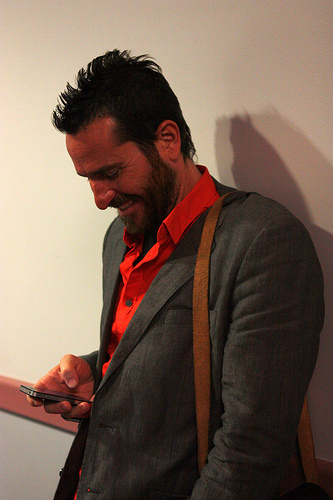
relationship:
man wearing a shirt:
[28, 45, 329, 499] [65, 156, 220, 499]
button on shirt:
[123, 296, 133, 307] [65, 156, 220, 499]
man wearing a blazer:
[28, 45, 329, 499] [44, 175, 328, 499]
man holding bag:
[28, 45, 329, 499] [191, 184, 323, 499]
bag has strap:
[191, 184, 323, 499] [191, 187, 318, 488]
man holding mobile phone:
[28, 45, 329, 499] [19, 382, 93, 409]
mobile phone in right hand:
[19, 382, 93, 409] [27, 354, 99, 422]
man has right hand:
[28, 45, 329, 499] [27, 354, 99, 422]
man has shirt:
[28, 45, 329, 499] [65, 156, 220, 499]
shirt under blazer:
[65, 156, 220, 499] [44, 175, 328, 499]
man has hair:
[28, 45, 329, 499] [52, 49, 199, 165]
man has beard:
[28, 45, 329, 499] [93, 164, 179, 237]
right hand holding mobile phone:
[27, 354, 99, 422] [19, 382, 93, 409]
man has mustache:
[28, 45, 329, 499] [106, 193, 144, 207]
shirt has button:
[65, 156, 220, 499] [123, 296, 133, 307]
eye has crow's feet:
[98, 170, 122, 180] [120, 153, 141, 176]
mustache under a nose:
[106, 193, 144, 207] [89, 178, 117, 216]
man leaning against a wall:
[28, 45, 329, 499] [1, 0, 333, 499]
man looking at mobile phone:
[28, 45, 329, 499] [19, 382, 93, 409]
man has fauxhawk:
[28, 45, 329, 499] [45, 49, 160, 124]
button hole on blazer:
[97, 421, 118, 433] [44, 175, 328, 499]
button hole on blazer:
[84, 486, 103, 497] [44, 175, 328, 499]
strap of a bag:
[191, 187, 318, 488] [191, 184, 323, 499]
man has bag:
[28, 45, 329, 499] [191, 184, 323, 499]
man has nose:
[28, 45, 329, 499] [89, 178, 117, 216]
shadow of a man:
[206, 104, 332, 475] [28, 45, 329, 499]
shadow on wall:
[206, 104, 332, 475] [1, 0, 333, 499]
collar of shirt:
[108, 160, 220, 242] [65, 156, 220, 499]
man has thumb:
[28, 45, 329, 499] [58, 356, 78, 390]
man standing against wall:
[28, 45, 329, 499] [1, 0, 333, 499]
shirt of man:
[65, 156, 220, 499] [28, 45, 329, 499]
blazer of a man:
[44, 175, 328, 499] [28, 45, 329, 499]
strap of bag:
[191, 187, 318, 488] [191, 184, 323, 499]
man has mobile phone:
[28, 45, 329, 499] [19, 382, 93, 409]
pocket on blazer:
[159, 308, 219, 337] [44, 175, 328, 499]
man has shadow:
[28, 45, 329, 499] [206, 104, 332, 475]